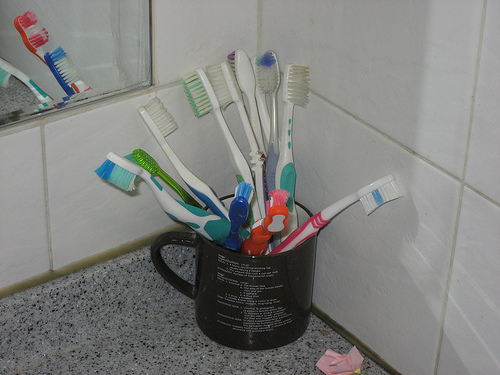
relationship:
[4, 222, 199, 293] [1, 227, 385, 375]
grout around a granite counter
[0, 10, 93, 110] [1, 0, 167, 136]
reflection in mirror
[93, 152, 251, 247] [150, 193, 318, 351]
tooth brush in coffee mug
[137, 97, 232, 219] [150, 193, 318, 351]
toothbrush in coffee mug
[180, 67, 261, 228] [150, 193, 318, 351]
toothbrush in coffee mug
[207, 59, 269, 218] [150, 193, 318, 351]
toothbrush in coffee mug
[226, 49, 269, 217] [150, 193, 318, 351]
toothbrush in coffee mug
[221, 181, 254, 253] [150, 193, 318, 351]
blue toothbrush in coffee mug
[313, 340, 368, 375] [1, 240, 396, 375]
paper on top of counter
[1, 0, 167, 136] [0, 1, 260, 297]
mirror hanging on wall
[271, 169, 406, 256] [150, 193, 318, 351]
toothbrush inside coffee mug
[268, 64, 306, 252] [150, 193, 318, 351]
toothbrush inside coffee mug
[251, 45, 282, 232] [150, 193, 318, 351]
toothbrush inside coffee mug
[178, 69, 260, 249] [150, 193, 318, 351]
toothbrush inside coffee mug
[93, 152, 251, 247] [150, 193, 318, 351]
tooth brush inside coffee mug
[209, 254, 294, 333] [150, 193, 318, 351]
white writing in coffee mug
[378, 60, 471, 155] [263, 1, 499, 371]
white tile on wall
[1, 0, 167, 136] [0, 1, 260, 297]
mirror on wall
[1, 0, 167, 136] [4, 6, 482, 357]
mirror hanging wall